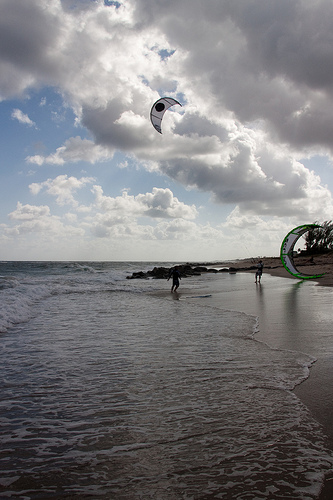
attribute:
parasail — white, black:
[150, 95, 179, 136]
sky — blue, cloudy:
[2, 3, 332, 263]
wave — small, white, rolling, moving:
[1, 283, 138, 333]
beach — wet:
[153, 253, 331, 425]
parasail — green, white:
[273, 222, 330, 285]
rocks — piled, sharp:
[122, 257, 246, 283]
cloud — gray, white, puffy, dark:
[128, 9, 319, 146]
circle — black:
[153, 100, 167, 114]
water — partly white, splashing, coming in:
[3, 260, 314, 499]